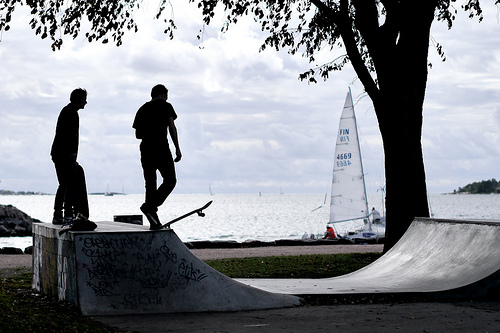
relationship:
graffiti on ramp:
[75, 235, 219, 312] [16, 198, 493, 328]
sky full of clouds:
[2, 2, 483, 191] [61, 28, 457, 162]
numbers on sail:
[330, 148, 367, 176] [316, 80, 380, 239]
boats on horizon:
[204, 180, 297, 201] [201, 178, 439, 198]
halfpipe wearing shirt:
[27, 216, 500, 312] [130, 98, 177, 144]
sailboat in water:
[12, 179, 285, 270] [70, 78, 371, 266]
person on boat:
[367, 207, 384, 229] [301, 86, 384, 241]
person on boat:
[322, 224, 339, 238] [301, 86, 384, 241]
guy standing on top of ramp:
[49, 86, 98, 234] [27, 213, 485, 320]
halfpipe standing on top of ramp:
[27, 216, 500, 312] [27, 213, 485, 320]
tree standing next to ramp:
[187, 0, 485, 258] [27, 213, 485, 320]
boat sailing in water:
[301, 86, 384, 241] [1, 190, 484, 247]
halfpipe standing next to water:
[27, 212, 484, 313] [1, 190, 484, 247]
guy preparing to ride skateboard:
[131, 85, 179, 230] [160, 198, 214, 230]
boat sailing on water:
[301, 82, 384, 241] [1, 190, 484, 247]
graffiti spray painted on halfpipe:
[75, 235, 219, 312] [27, 212, 484, 313]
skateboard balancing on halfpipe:
[160, 198, 214, 230] [27, 212, 484, 313]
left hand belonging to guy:
[172, 148, 184, 164] [131, 85, 179, 230]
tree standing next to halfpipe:
[187, 0, 485, 258] [27, 212, 484, 313]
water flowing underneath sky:
[1, 190, 484, 247] [2, 2, 483, 191]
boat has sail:
[301, 86, 384, 241] [320, 80, 376, 236]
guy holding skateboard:
[49, 86, 103, 234] [62, 151, 93, 221]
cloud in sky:
[0, 0, 500, 195] [2, 2, 497, 250]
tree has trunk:
[187, 0, 486, 260] [365, 108, 433, 222]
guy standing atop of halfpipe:
[131, 85, 179, 230] [27, 216, 500, 312]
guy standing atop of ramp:
[49, 86, 98, 234] [38, 218, 266, 317]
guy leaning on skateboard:
[131, 85, 179, 230] [160, 198, 214, 230]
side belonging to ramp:
[72, 230, 305, 317] [27, 213, 485, 320]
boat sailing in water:
[301, 82, 384, 241] [1, 190, 484, 247]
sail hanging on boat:
[327, 90, 368, 222] [301, 82, 384, 241]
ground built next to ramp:
[87, 300, 485, 330] [27, 213, 485, 320]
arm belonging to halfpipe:
[166, 103, 182, 163] [27, 216, 500, 312]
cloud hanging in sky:
[267, 138, 284, 154] [2, 2, 483, 191]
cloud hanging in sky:
[0, 0, 500, 195] [2, 2, 483, 191]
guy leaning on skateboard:
[131, 81, 181, 231] [160, 198, 214, 230]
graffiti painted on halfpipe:
[75, 235, 207, 307] [27, 216, 500, 312]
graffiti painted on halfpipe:
[75, 235, 219, 312] [27, 216, 500, 312]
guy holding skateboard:
[49, 86, 98, 234] [67, 161, 88, 220]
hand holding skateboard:
[73, 160, 79, 165] [67, 161, 88, 220]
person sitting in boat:
[322, 224, 340, 242] [301, 86, 384, 241]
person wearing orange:
[322, 224, 340, 242] [323, 226, 335, 239]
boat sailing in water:
[301, 86, 384, 241] [1, 192, 500, 245]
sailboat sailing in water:
[367, 187, 386, 225] [1, 192, 500, 245]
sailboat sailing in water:
[201, 183, 219, 197] [1, 192, 500, 245]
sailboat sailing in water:
[277, 186, 286, 196] [1, 192, 500, 245]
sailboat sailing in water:
[119, 186, 126, 194] [1, 192, 500, 245]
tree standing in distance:
[452, 189, 457, 193] [0, 173, 484, 205]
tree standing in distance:
[452, 189, 456, 193] [0, 173, 484, 205]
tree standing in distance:
[470, 184, 475, 193] [0, 173, 484, 205]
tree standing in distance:
[469, 181, 473, 189] [0, 173, 484, 205]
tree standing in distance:
[463, 186, 466, 192] [0, 173, 484, 205]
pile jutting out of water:
[0, 202, 45, 238] [1, 192, 500, 245]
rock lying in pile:
[1, 225, 11, 235] [0, 202, 45, 238]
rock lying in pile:
[14, 223, 26, 236] [0, 202, 45, 238]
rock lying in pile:
[6, 219, 22, 229] [0, 202, 45, 238]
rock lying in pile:
[16, 210, 28, 222] [0, 202, 45, 238]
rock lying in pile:
[30, 217, 42, 224] [0, 202, 45, 238]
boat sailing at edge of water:
[301, 86, 384, 241] [1, 190, 484, 247]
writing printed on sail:
[334, 125, 353, 167] [327, 90, 368, 222]